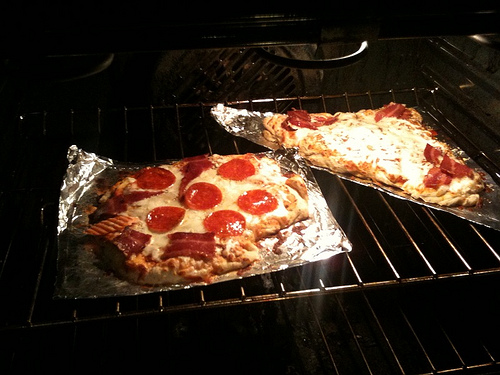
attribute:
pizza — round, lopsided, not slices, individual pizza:
[56, 145, 315, 289]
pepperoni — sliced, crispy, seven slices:
[133, 157, 278, 244]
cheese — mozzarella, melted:
[115, 161, 289, 258]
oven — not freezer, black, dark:
[0, 0, 500, 374]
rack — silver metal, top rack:
[1, 84, 500, 334]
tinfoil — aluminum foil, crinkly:
[42, 93, 498, 305]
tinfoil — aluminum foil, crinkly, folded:
[47, 140, 356, 304]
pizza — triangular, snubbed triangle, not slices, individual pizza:
[261, 97, 489, 211]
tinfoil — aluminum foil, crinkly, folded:
[205, 97, 498, 235]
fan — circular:
[146, 35, 325, 144]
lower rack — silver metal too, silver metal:
[145, 120, 498, 374]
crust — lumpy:
[86, 146, 312, 290]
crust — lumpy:
[259, 96, 490, 212]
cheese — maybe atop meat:
[302, 115, 443, 185]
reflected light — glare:
[59, 146, 352, 270]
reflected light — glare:
[206, 97, 274, 138]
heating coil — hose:
[31, 53, 124, 91]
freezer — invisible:
[262, 4, 267, 8]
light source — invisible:
[468, 34, 480, 44]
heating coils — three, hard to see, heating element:
[15, 14, 499, 86]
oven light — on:
[255, 44, 482, 70]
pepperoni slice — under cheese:
[181, 155, 213, 163]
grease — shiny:
[155, 192, 270, 235]